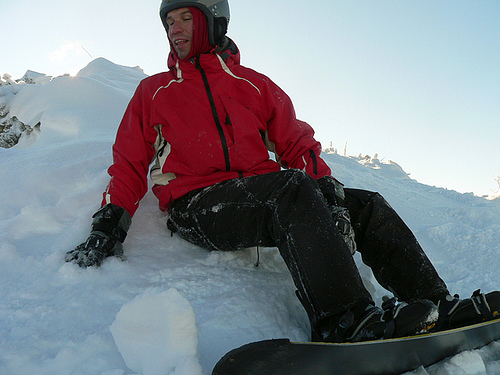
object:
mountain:
[0, 56, 135, 136]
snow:
[0, 56, 500, 373]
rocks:
[9, 115, 43, 144]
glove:
[63, 203, 132, 270]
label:
[101, 188, 113, 206]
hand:
[63, 200, 134, 270]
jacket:
[102, 53, 334, 213]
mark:
[219, 94, 234, 127]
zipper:
[188, 58, 231, 175]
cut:
[145, 121, 179, 199]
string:
[254, 240, 262, 270]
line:
[213, 51, 264, 99]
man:
[62, 0, 500, 345]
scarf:
[187, 5, 218, 58]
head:
[158, 0, 231, 64]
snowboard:
[210, 319, 500, 374]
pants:
[164, 169, 450, 330]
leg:
[210, 168, 376, 325]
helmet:
[160, 0, 231, 50]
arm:
[102, 103, 160, 248]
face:
[165, 12, 200, 52]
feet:
[311, 277, 497, 346]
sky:
[0, 1, 500, 203]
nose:
[167, 20, 186, 34]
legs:
[200, 169, 450, 299]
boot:
[317, 299, 437, 345]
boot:
[420, 289, 500, 335]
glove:
[320, 173, 358, 257]